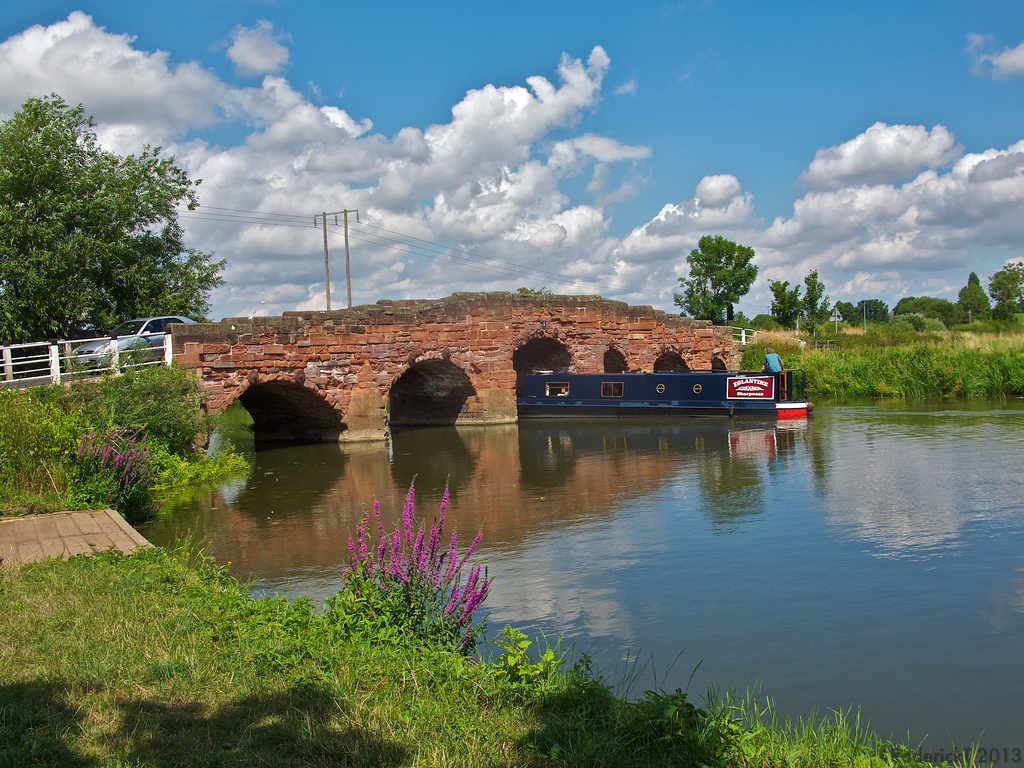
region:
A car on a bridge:
[72, 310, 199, 369]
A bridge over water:
[177, 292, 738, 451]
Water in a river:
[116, 409, 1021, 757]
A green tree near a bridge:
[0, 90, 204, 331]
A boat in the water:
[526, 364, 783, 422]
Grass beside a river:
[8, 367, 955, 764]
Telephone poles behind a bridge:
[311, 203, 370, 303]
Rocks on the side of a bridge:
[318, 336, 394, 381]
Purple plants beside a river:
[331, 475, 496, 632]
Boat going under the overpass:
[517, 356, 816, 430]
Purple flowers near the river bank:
[337, 464, 511, 667]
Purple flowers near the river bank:
[59, 418, 159, 486]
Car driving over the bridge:
[53, 304, 208, 363]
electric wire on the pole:
[132, 189, 556, 288]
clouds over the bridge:
[224, 73, 377, 187]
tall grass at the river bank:
[802, 341, 1002, 396]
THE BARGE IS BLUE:
[490, 349, 819, 435]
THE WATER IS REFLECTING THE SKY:
[111, 374, 1012, 754]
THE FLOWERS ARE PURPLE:
[315, 453, 508, 665]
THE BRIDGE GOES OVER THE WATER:
[166, 296, 755, 468]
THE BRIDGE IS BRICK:
[150, 275, 784, 479]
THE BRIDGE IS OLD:
[159, 242, 793, 518]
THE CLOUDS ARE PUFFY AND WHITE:
[4, 12, 1022, 377]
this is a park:
[108, 110, 991, 739]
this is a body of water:
[339, 361, 1008, 744]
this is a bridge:
[275, 297, 520, 428]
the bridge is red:
[225, 241, 617, 463]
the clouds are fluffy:
[178, 72, 485, 338]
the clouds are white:
[187, 72, 529, 393]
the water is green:
[255, 389, 1023, 740]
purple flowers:
[334, 490, 503, 645]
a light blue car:
[65, 309, 208, 377]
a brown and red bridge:
[170, 291, 739, 441]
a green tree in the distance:
[672, 225, 752, 330]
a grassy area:
[27, 556, 253, 740]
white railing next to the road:
[9, 337, 169, 388]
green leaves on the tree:
[114, 215, 157, 258]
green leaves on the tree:
[50, 221, 98, 289]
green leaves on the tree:
[116, 239, 162, 320]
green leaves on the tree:
[114, 123, 185, 199]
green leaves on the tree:
[694, 234, 737, 304]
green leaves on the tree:
[853, 269, 882, 317]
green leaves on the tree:
[948, 261, 1009, 339]